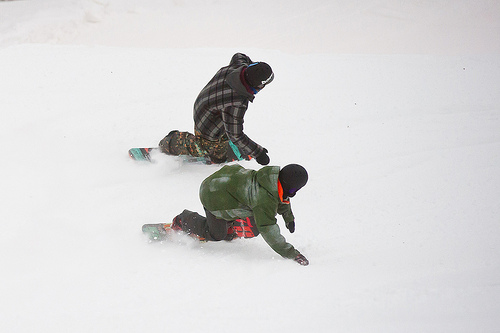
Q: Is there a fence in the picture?
A: No, there are no fences.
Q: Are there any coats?
A: Yes, there is a coat.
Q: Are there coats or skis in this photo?
A: Yes, there is a coat.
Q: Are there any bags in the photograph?
A: No, there are no bags.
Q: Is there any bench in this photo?
A: No, there are no benches.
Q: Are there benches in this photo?
A: No, there are no benches.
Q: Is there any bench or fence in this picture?
A: No, there are no benches or fences.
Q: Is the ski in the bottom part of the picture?
A: Yes, the ski is in the bottom of the image.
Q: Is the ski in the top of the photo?
A: No, the ski is in the bottom of the image.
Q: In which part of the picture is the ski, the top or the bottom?
A: The ski is in the bottom of the image.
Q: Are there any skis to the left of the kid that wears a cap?
A: Yes, there is a ski to the left of the child.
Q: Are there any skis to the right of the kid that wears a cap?
A: No, the ski is to the left of the child.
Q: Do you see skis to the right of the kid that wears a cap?
A: No, the ski is to the left of the child.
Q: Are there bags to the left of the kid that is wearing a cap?
A: No, there is a ski to the left of the child.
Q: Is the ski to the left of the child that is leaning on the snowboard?
A: Yes, the ski is to the left of the child.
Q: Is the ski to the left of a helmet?
A: No, the ski is to the left of the child.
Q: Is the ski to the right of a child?
A: No, the ski is to the left of a child.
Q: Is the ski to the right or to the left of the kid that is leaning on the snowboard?
A: The ski is to the left of the kid.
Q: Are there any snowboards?
A: Yes, there is a snowboard.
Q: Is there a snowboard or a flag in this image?
A: Yes, there is a snowboard.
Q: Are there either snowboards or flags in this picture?
A: Yes, there is a snowboard.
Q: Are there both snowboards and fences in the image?
A: No, there is a snowboard but no fences.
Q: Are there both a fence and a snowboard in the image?
A: No, there is a snowboard but no fences.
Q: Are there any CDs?
A: No, there are no cds.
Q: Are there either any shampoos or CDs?
A: No, there are no CDs or shampoos.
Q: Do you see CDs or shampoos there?
A: No, there are no CDs or shampoos.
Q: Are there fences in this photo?
A: No, there are no fences.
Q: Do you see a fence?
A: No, there are no fences.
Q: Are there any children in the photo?
A: Yes, there is a child.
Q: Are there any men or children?
A: Yes, there is a child.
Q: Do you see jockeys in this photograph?
A: No, there are no jockeys.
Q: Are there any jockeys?
A: No, there are no jockeys.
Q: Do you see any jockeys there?
A: No, there are no jockeys.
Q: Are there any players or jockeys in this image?
A: No, there are no jockeys or players.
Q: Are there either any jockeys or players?
A: No, there are no jockeys or players.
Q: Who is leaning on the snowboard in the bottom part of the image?
A: The kid is leaning on the snowboard.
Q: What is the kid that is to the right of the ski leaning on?
A: The child is leaning on the snowboard.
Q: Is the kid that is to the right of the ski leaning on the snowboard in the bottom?
A: Yes, the kid is leaning on the snow board.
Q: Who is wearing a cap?
A: The kid is wearing a cap.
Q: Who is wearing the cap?
A: The kid is wearing a cap.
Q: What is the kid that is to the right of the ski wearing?
A: The child is wearing a cap.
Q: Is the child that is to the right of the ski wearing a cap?
A: Yes, the kid is wearing a cap.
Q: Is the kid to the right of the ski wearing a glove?
A: No, the kid is wearing a cap.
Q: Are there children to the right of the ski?
A: Yes, there is a child to the right of the ski.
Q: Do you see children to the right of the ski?
A: Yes, there is a child to the right of the ski.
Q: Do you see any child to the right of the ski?
A: Yes, there is a child to the right of the ski.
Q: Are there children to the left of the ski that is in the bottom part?
A: No, the child is to the right of the ski.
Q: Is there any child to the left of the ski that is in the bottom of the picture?
A: No, the child is to the right of the ski.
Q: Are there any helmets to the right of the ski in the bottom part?
A: No, there is a child to the right of the ski.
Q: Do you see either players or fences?
A: No, there are no fences or players.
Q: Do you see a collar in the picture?
A: Yes, there is a collar.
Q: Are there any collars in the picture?
A: Yes, there is a collar.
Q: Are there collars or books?
A: Yes, there is a collar.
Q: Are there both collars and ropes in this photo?
A: No, there is a collar but no ropes.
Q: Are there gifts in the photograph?
A: No, there are no gifts.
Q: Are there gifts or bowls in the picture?
A: No, there are no gifts or bowls.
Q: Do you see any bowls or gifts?
A: No, there are no gifts or bowls.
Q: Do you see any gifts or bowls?
A: No, there are no gifts or bowls.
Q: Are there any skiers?
A: No, there are no skiers.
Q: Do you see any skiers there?
A: No, there are no skiers.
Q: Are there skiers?
A: No, there are no skiers.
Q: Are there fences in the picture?
A: No, there are no fences.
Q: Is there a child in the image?
A: Yes, there is a child.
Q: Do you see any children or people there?
A: Yes, there is a child.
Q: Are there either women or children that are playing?
A: Yes, the child is playing.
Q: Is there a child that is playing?
A: Yes, there is a child that is playing.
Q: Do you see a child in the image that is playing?
A: Yes, there is a child that is playing.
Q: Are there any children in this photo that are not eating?
A: Yes, there is a child that is playing.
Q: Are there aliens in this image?
A: No, there are no aliens.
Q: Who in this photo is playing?
A: The child is playing.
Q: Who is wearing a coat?
A: The child is wearing a coat.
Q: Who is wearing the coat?
A: The child is wearing a coat.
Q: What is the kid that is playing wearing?
A: The kid is wearing a coat.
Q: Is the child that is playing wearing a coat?
A: Yes, the kid is wearing a coat.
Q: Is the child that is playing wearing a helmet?
A: No, the child is wearing a coat.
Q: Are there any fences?
A: No, there are no fences.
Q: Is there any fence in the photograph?
A: No, there are no fences.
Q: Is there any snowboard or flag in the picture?
A: Yes, there is a snowboard.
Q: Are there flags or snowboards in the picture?
A: Yes, there is a snowboard.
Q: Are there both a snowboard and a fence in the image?
A: No, there is a snowboard but no fences.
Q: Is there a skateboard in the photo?
A: No, there are no skateboards.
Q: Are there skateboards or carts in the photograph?
A: No, there are no skateboards or carts.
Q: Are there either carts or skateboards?
A: No, there are no skateboards or carts.